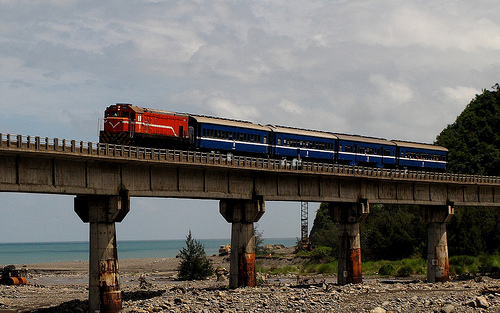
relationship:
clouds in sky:
[0, 0, 500, 145] [12, 27, 458, 102]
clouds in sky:
[0, 0, 500, 145] [10, 23, 164, 89]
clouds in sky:
[0, 0, 500, 145] [296, 22, 493, 95]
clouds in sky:
[235, 17, 445, 119] [10, 18, 95, 115]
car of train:
[185, 109, 274, 159] [93, 96, 469, 181]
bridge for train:
[5, 130, 496, 300] [96, 99, 451, 177]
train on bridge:
[96, 99, 451, 177] [98, 101, 471, 206]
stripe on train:
[200, 133, 455, 165] [82, 98, 462, 185]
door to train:
[175, 121, 185, 138] [96, 99, 451, 177]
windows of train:
[203, 123, 261, 144] [96, 99, 451, 177]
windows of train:
[276, 134, 335, 151] [96, 99, 451, 177]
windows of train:
[336, 141, 393, 158] [96, 99, 451, 177]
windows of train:
[397, 146, 450, 165] [96, 99, 451, 177]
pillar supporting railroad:
[229, 219, 256, 288] [5, 132, 485, 182]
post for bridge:
[75, 196, 132, 311] [5, 130, 496, 300]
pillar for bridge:
[229, 219, 256, 288] [5, 130, 496, 300]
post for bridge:
[334, 192, 371, 282] [5, 130, 496, 300]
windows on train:
[208, 123, 270, 149] [95, 106, 460, 172]